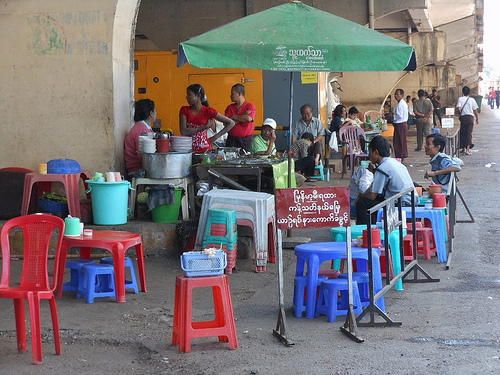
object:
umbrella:
[177, 0, 417, 188]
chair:
[3, 212, 69, 362]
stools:
[202, 209, 241, 251]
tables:
[56, 230, 146, 301]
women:
[176, 82, 235, 155]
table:
[194, 149, 292, 194]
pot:
[206, 140, 240, 166]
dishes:
[165, 133, 197, 154]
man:
[249, 115, 278, 153]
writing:
[278, 185, 349, 232]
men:
[355, 133, 419, 226]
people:
[422, 133, 465, 199]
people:
[389, 86, 410, 158]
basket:
[179, 248, 229, 279]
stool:
[171, 273, 239, 354]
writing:
[266, 45, 333, 73]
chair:
[75, 258, 117, 304]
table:
[291, 240, 384, 315]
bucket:
[363, 227, 383, 248]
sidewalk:
[291, 89, 500, 374]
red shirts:
[179, 103, 215, 151]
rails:
[410, 181, 422, 263]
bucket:
[85, 178, 130, 225]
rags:
[92, 167, 104, 180]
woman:
[179, 81, 235, 152]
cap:
[264, 119, 278, 130]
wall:
[0, 0, 140, 179]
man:
[223, 82, 256, 140]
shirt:
[225, 98, 259, 139]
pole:
[288, 76, 299, 192]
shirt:
[251, 134, 280, 156]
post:
[438, 114, 460, 150]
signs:
[446, 107, 455, 117]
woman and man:
[178, 70, 257, 152]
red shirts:
[124, 123, 156, 176]